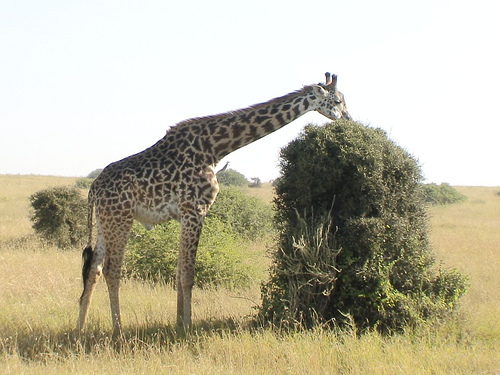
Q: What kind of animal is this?
A: Giraffe.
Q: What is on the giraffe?
A: Brown spots.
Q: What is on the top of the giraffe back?
A: Mane.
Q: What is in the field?
A: Yellowed grass.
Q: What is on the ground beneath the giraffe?
A: Shadow.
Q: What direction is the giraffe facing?
A: Right.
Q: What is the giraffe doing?
A: Standing up.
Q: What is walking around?
A: The giraffe.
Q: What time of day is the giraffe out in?
A: The daytime.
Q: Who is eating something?
A: The giraffe.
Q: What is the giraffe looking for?
A: Food.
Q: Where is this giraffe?
A: In a field.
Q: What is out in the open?
A: A giraffe.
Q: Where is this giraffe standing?
A: In tall grass.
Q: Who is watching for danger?
A: The giraffe.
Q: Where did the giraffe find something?
A: On a bush.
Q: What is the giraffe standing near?
A: A bush.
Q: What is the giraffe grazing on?
A: A bush.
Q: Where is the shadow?
A: On the grass.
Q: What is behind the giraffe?
A: A bush.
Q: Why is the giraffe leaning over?
A: Grazing.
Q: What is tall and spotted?
A: Giraffe.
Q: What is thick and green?
A: A bush.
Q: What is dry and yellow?
A: Grass.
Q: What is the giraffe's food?
A: The bush.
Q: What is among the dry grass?
A: Green bushes.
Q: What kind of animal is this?
A: Giraffe.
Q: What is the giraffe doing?
A: Grazing bush.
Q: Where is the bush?
A: In the field.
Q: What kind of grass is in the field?
A: Yellowed grass.